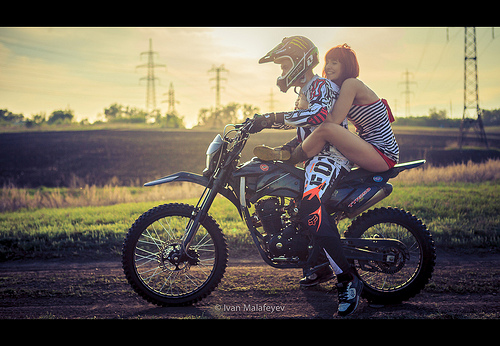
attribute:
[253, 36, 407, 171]
couple — young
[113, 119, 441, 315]
bike — black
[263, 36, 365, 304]
gear — protective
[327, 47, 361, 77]
hair — dark, short, red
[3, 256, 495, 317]
road — dirt, gravel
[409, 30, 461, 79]
wiring — electric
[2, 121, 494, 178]
field — plowed, large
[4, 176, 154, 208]
grass — tall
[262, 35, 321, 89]
helmet — dark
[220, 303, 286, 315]
name — white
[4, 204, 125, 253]
grass — green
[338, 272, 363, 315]
shoe — white, black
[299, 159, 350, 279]
pants — black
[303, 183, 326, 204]
splash — orange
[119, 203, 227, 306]
tire — black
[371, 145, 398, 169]
shorts — red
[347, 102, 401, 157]
top — striped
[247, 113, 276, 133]
glove — black